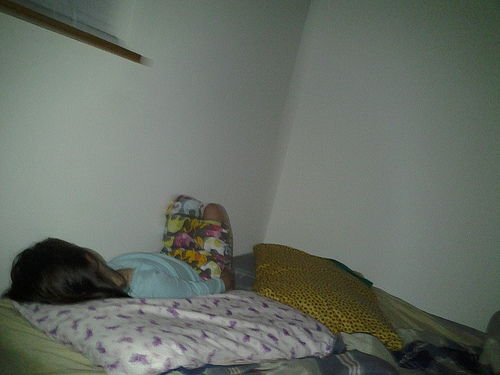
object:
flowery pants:
[160, 193, 234, 277]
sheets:
[1, 296, 107, 374]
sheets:
[372, 287, 491, 348]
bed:
[2, 253, 494, 373]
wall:
[256, 0, 499, 335]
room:
[2, 0, 499, 374]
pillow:
[253, 242, 402, 351]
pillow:
[13, 288, 347, 374]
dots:
[323, 301, 328, 304]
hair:
[0, 237, 135, 305]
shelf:
[0, 0, 141, 65]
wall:
[0, 0, 315, 293]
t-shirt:
[107, 252, 225, 298]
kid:
[0, 193, 235, 303]